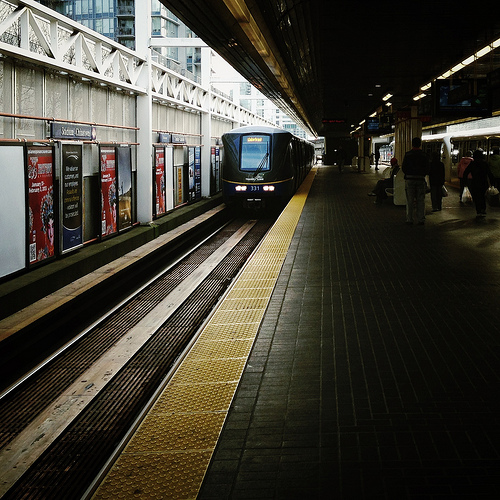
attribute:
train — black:
[206, 123, 315, 208]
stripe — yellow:
[219, 174, 292, 188]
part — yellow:
[86, 157, 323, 499]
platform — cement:
[280, 183, 421, 440]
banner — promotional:
[188, 145, 196, 202]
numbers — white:
[239, 175, 268, 196]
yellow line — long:
[128, 160, 318, 497]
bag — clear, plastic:
[486, 183, 498, 200]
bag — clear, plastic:
[458, 185, 474, 203]